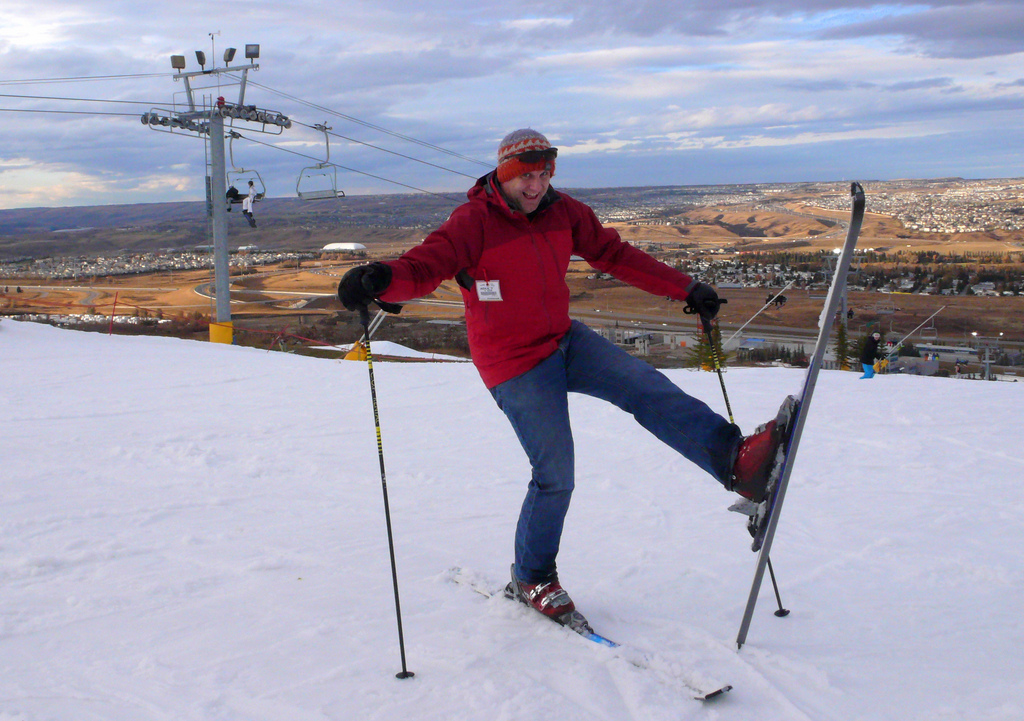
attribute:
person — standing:
[341, 127, 803, 617]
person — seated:
[234, 174, 260, 229]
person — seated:
[239, 175, 263, 223]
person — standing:
[854, 327, 883, 382]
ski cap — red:
[492, 123, 557, 180]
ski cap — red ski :
[868, 327, 882, 341]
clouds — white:
[0, 22, 816, 98]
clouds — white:
[29, 168, 118, 201]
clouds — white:
[302, 16, 524, 93]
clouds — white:
[536, 38, 824, 68]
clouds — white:
[574, 71, 729, 114]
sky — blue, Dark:
[0, 0, 1019, 197]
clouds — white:
[743, 101, 813, 139]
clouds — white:
[819, 54, 909, 140]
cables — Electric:
[2, 46, 477, 203]